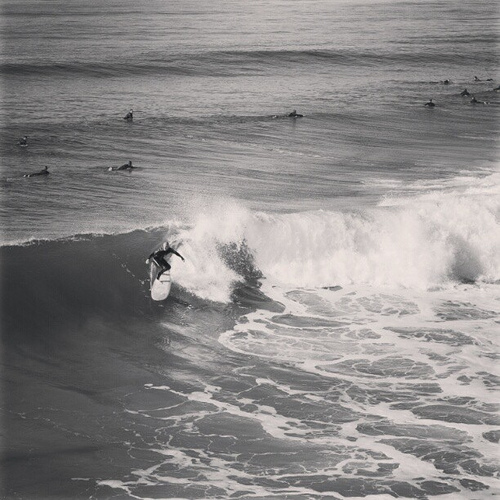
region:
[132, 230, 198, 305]
a man surfing on the wave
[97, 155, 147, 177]
a man swimming on the surf board trying to catch a wave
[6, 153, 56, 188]
a man trying to catch a wave to surf on it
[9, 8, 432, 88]
a wave tide nearing the shore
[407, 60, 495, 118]
people trying to find a wave to surf on it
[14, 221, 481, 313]
a guy surfing on a wave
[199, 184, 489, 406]
wave nearing the sea shore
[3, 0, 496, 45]
sea looks calm with rare tides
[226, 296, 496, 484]
white foam formation by the wave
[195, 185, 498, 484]
wave approaching the shore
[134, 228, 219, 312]
this is a person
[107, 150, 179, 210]
this is a person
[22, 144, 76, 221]
this is a person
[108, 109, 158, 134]
this is a person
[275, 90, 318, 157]
this is a person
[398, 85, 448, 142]
this is a person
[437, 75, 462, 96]
this is a person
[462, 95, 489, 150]
this is a person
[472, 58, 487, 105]
this is a person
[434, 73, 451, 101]
this is a person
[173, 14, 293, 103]
Water in the ocean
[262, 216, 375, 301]
Waves in the photo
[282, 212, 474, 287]
Strong tides of the ocean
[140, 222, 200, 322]
A person surfing in the water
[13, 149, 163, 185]
People lying on the water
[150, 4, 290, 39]
Calm waters in the photo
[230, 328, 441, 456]
Ocean waters in the photo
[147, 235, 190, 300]
A person in the air surfing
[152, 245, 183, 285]
Black surfwear in the photo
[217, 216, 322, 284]
Violent ocean waters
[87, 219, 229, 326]
Person in the water.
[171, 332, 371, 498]
White waves in the water.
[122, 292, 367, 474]
Waves in the water.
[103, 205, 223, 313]
Person on a surfboard.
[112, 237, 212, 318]
White surfboard on the water.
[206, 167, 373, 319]
White spray on the water.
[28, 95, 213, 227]
People in the background.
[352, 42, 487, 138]
People in the water.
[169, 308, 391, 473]
Ripples in the water.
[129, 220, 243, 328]
Man in a wetsuit.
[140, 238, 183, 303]
Person in a wetsuit on a surf board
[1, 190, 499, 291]
breaking wave with sea foam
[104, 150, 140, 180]
person laying on surfboard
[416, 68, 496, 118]
group of people laying on surfboards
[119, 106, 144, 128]
person sitting up on surfboard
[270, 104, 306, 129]
person paddling on surfboard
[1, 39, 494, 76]
wave coming in and about to break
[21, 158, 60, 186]
person laying on surfboard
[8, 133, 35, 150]
person laying on surfboard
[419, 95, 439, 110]
person swimming in the water